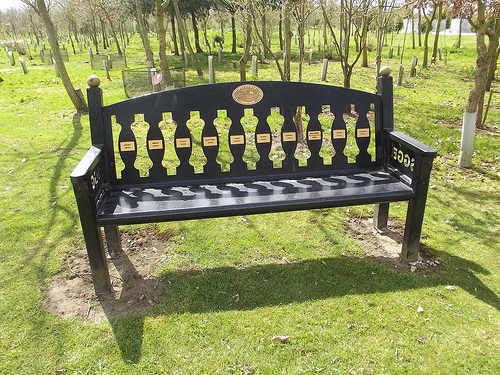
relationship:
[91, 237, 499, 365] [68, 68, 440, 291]
shadow of a bench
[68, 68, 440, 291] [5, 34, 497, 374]
bench on grass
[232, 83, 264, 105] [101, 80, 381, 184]
symbol on top of backrest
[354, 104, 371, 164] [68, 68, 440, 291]
plaques on bench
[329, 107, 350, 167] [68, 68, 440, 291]
plaques on bench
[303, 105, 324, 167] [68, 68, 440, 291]
plaques on bench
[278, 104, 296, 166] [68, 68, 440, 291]
plaques on bench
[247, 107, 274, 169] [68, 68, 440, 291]
plaques on bench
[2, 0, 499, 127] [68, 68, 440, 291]
plants behind a bench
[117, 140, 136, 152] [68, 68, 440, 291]
plaque on bench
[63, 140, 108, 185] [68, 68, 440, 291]
arm of bench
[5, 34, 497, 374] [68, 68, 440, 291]
grass under bench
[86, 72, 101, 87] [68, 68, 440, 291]
ball atop bench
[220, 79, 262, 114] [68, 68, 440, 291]
symbol on bench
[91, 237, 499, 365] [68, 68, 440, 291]
shadow under bench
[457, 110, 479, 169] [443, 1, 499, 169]
white pipe around tree